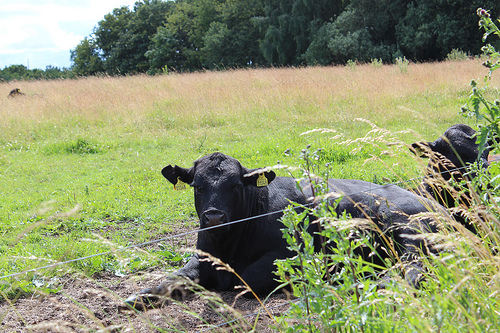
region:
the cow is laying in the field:
[161, 152, 473, 298]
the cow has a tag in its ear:
[255, 172, 271, 194]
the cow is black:
[156, 151, 473, 298]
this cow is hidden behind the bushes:
[411, 120, 491, 209]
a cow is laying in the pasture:
[6, 85, 27, 99]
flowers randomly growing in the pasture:
[278, 141, 361, 330]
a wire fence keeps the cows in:
[2, 162, 433, 281]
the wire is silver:
[2, 208, 254, 275]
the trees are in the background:
[92, 0, 497, 66]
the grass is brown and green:
[7, 60, 492, 137]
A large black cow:
[131, 135, 483, 322]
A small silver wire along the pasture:
[0, 171, 364, 318]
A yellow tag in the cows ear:
[244, 163, 280, 196]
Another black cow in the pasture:
[0, 82, 62, 129]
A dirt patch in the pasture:
[17, 269, 247, 331]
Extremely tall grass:
[53, 72, 437, 146]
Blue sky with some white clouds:
[4, 36, 71, 68]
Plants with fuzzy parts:
[451, 40, 498, 242]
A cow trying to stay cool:
[394, 104, 494, 216]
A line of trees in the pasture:
[76, 6, 498, 60]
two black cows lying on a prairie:
[147, 113, 499, 312]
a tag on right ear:
[226, 150, 291, 200]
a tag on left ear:
[151, 148, 206, 198]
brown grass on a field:
[1, 56, 499, 126]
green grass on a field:
[5, 103, 499, 298]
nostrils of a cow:
[196, 201, 234, 233]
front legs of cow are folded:
[181, 243, 299, 294]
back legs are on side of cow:
[371, 197, 454, 314]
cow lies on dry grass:
[136, 150, 471, 327]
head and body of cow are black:
[144, 137, 456, 303]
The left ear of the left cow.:
[162, 159, 194, 191]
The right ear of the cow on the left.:
[244, 169, 278, 184]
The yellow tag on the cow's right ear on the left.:
[253, 172, 270, 186]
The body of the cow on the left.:
[268, 176, 481, 287]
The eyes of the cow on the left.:
[189, 174, 248, 194]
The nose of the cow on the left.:
[189, 206, 229, 225]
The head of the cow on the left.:
[151, 151, 271, 244]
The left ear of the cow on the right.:
[411, 128, 431, 158]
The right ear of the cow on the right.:
[486, 131, 497, 146]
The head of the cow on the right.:
[426, 117, 497, 173]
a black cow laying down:
[152, 147, 461, 293]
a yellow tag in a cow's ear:
[254, 170, 272, 188]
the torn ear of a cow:
[159, 162, 197, 189]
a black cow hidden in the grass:
[5, 84, 30, 102]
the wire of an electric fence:
[3, 155, 492, 295]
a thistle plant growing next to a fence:
[460, 5, 499, 168]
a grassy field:
[0, 55, 497, 328]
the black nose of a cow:
[198, 209, 231, 231]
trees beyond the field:
[79, 0, 498, 76]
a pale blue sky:
[0, 0, 136, 70]